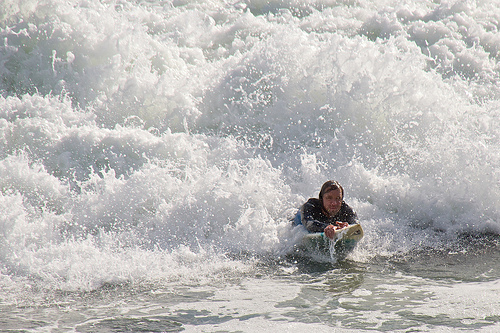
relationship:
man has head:
[295, 178, 354, 238] [318, 182, 345, 221]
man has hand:
[295, 178, 354, 238] [323, 223, 340, 239]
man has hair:
[295, 178, 354, 238] [318, 178, 345, 217]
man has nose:
[295, 178, 354, 238] [330, 199, 339, 208]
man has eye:
[295, 178, 354, 238] [323, 196, 335, 201]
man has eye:
[295, 178, 354, 238] [336, 197, 342, 204]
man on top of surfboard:
[295, 178, 354, 238] [307, 222, 365, 265]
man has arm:
[295, 178, 354, 238] [302, 203, 336, 238]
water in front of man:
[6, 231, 500, 332] [295, 178, 354, 238]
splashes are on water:
[32, 233, 246, 296] [6, 231, 500, 332]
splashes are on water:
[365, 218, 454, 264] [6, 231, 500, 332]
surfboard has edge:
[307, 222, 365, 265] [305, 223, 364, 248]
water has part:
[6, 231, 500, 332] [377, 263, 447, 323]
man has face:
[295, 178, 354, 238] [328, 190, 345, 212]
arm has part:
[302, 203, 336, 238] [306, 208, 312, 221]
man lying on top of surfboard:
[295, 178, 354, 238] [307, 222, 365, 265]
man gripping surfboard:
[295, 178, 354, 238] [307, 222, 365, 265]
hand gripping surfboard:
[323, 223, 340, 239] [307, 222, 365, 265]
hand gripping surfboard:
[334, 219, 351, 230] [307, 222, 365, 265]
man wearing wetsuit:
[295, 178, 354, 238] [290, 197, 353, 233]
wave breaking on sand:
[1, 5, 496, 288] [1, 232, 497, 329]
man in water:
[295, 178, 354, 238] [6, 231, 500, 332]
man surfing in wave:
[295, 178, 354, 238] [1, 5, 496, 288]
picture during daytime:
[0, 2, 499, 323] [0, 1, 499, 319]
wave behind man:
[1, 5, 496, 288] [295, 178, 354, 238]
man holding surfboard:
[295, 178, 354, 238] [307, 222, 365, 265]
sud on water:
[173, 271, 303, 333] [6, 231, 500, 332]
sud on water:
[352, 274, 499, 332] [6, 231, 500, 332]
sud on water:
[12, 289, 160, 333] [6, 231, 500, 332]